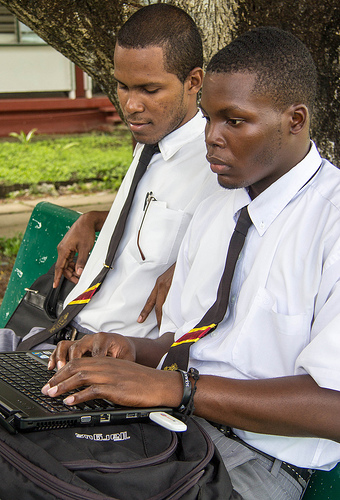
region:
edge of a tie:
[209, 302, 226, 335]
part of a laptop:
[60, 390, 106, 461]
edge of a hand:
[147, 394, 161, 408]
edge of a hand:
[130, 407, 155, 446]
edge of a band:
[178, 392, 183, 401]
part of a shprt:
[236, 417, 257, 464]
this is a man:
[164, 54, 304, 446]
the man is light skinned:
[158, 86, 176, 100]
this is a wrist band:
[178, 365, 192, 405]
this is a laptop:
[14, 347, 48, 413]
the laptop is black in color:
[20, 395, 43, 422]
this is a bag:
[61, 439, 212, 490]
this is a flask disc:
[153, 409, 184, 435]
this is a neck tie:
[202, 238, 236, 337]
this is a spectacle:
[132, 187, 154, 265]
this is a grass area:
[42, 135, 79, 171]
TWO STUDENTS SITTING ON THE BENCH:
[0, 7, 335, 370]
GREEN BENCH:
[5, 188, 330, 498]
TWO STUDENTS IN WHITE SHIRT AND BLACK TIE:
[36, 3, 338, 463]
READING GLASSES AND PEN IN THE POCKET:
[130, 187, 180, 271]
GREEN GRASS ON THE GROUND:
[3, 135, 163, 188]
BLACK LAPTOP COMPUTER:
[0, 335, 187, 439]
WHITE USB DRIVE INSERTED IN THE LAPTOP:
[136, 397, 187, 435]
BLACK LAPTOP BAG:
[0, 410, 267, 498]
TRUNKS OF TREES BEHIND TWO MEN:
[8, 1, 339, 160]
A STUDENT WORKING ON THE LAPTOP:
[0, 18, 336, 433]